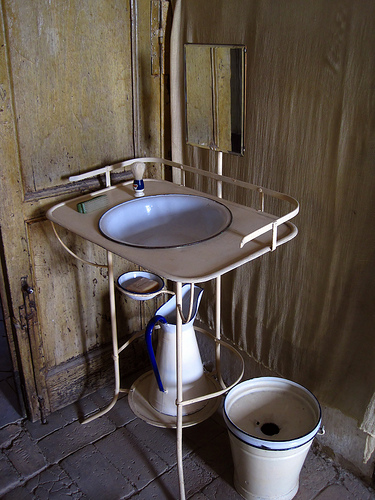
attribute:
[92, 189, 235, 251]
washbowl — small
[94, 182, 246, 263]
sink — white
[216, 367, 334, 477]
pail — white, metal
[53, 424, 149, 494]
floor — concrete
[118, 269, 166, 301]
soap dish — under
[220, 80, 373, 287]
area — curtain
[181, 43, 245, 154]
mirror — above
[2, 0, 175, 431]
wall — wood, worn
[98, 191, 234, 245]
sink — water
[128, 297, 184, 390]
handle — blue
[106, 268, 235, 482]
pitcher — white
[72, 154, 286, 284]
sink — small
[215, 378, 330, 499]
trashcan — beside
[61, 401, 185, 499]
floor — concrete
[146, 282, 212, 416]
pitcher — white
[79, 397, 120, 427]
support — metal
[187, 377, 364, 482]
pail — metal